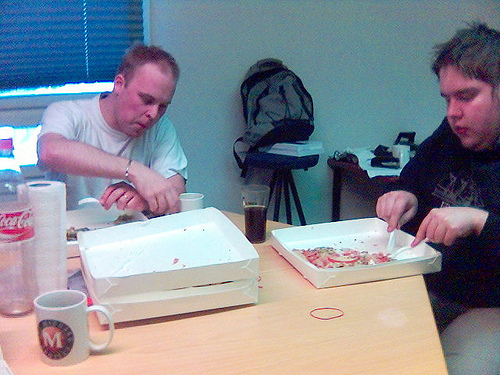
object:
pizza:
[291, 247, 400, 269]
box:
[268, 216, 443, 289]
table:
[0, 208, 451, 375]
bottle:
[0, 137, 35, 314]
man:
[37, 45, 187, 214]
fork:
[78, 197, 116, 206]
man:
[376, 21, 500, 337]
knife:
[384, 229, 398, 251]